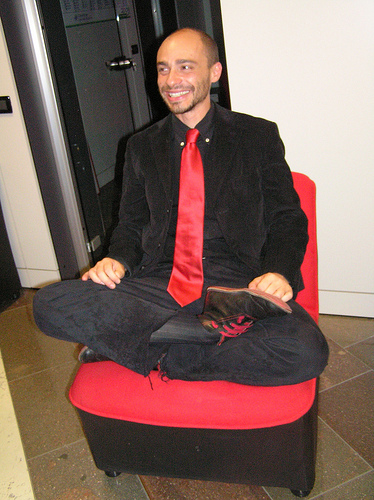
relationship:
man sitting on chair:
[32, 27, 329, 389] [67, 170, 319, 498]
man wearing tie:
[32, 27, 329, 389] [165, 130, 205, 307]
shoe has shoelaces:
[196, 285, 292, 349] [206, 315, 253, 342]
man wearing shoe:
[32, 27, 329, 389] [196, 285, 292, 349]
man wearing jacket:
[32, 27, 329, 389] [103, 100, 308, 291]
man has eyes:
[32, 27, 329, 389] [158, 64, 193, 74]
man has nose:
[32, 27, 329, 389] [166, 68, 181, 91]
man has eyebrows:
[32, 27, 329, 389] [154, 57, 200, 66]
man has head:
[32, 27, 329, 389] [151, 27, 223, 113]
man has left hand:
[32, 27, 329, 389] [247, 270, 295, 301]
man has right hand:
[32, 27, 329, 389] [78, 255, 127, 291]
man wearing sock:
[32, 27, 329, 389] [148, 311, 221, 346]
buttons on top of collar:
[178, 135, 210, 146] [171, 99, 213, 146]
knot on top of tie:
[182, 127, 198, 145] [165, 130, 205, 307]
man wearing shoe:
[32, 27, 329, 389] [75, 343, 160, 373]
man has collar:
[32, 27, 329, 389] [171, 99, 213, 146]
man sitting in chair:
[32, 27, 329, 389] [67, 170, 319, 498]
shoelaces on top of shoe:
[206, 315, 253, 342] [196, 285, 292, 349]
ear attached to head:
[209, 60, 223, 87] [151, 27, 223, 113]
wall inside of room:
[0, 0, 372, 319] [1, 0, 372, 498]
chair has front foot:
[67, 170, 319, 498] [291, 487, 310, 498]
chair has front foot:
[67, 170, 319, 498] [103, 467, 123, 478]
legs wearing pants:
[31, 277, 329, 387] [31, 272, 327, 384]